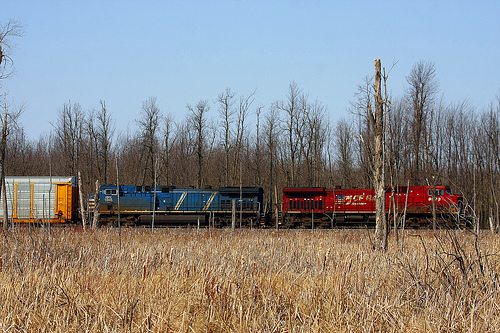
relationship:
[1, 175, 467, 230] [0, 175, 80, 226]
locomotives has a car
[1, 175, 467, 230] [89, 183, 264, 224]
locomotives has a car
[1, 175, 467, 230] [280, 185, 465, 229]
locomotives has a car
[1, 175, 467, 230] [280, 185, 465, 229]
locomotives has a drivers car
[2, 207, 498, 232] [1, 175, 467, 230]
fence runs along beside a locomotives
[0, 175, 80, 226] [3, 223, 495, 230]
car on tracks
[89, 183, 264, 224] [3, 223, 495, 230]
car on tracks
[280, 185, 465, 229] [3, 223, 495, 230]
car on tracks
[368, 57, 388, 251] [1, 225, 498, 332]
tree standing in field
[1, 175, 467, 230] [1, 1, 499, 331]
locomotives in photograph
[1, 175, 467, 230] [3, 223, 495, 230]
locomotives sitting on tracks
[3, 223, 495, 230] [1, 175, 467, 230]
tracks are below locomotives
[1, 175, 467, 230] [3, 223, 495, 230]
locomotives on tracks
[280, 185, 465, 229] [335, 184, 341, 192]
car has a smoke stack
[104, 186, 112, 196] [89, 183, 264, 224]
window on back of car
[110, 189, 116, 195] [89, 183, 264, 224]
window on back of car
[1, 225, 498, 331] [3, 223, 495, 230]
grass beside tracks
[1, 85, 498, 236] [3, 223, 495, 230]
trees are near to tracks